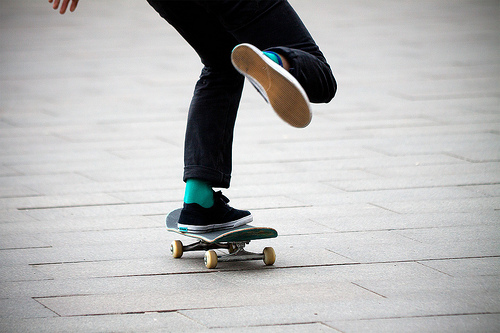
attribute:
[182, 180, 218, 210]
sock — green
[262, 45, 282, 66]
sock — green, blue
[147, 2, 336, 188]
pants — black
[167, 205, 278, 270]
skateboard — black, wooden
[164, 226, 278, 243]
edge — tan, white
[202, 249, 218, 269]
wheel — tan, white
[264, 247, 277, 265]
wheel — tan, white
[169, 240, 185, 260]
wheel — tan, white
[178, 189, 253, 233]
sneaker — black, blac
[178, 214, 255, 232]
edge — white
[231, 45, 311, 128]
sole — tan, dirty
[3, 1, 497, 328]
ground — concrete, gray, squared, stone, floor, clean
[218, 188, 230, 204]
shoelace — black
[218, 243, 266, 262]
axle — metal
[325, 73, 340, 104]
knee — bent